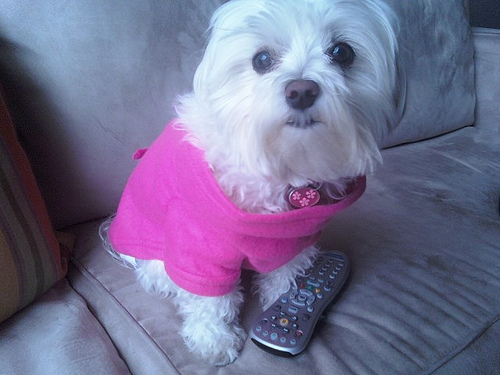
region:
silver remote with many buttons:
[247, 245, 355, 360]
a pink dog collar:
[289, 178, 325, 208]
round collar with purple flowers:
[283, 175, 324, 215]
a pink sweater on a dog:
[103, 117, 370, 277]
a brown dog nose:
[282, 75, 317, 112]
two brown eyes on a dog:
[253, 39, 357, 72]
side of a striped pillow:
[2, 93, 68, 319]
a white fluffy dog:
[103, 2, 412, 364]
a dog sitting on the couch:
[2, 1, 492, 371]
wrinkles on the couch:
[310, 253, 497, 373]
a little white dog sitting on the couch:
[97, 0, 408, 367]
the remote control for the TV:
[247, 245, 354, 360]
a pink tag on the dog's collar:
[285, 184, 323, 209]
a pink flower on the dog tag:
[290, 190, 302, 201]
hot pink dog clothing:
[103, 117, 370, 302]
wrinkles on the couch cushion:
[306, 249, 493, 374]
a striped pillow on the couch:
[0, 95, 72, 326]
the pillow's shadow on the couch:
[0, 35, 93, 231]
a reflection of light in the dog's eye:
[260, 55, 268, 64]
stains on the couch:
[421, 182, 498, 228]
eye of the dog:
[308, 34, 359, 59]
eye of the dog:
[246, 43, 277, 66]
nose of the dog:
[265, 70, 314, 110]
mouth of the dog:
[282, 115, 320, 132]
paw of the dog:
[207, 333, 244, 362]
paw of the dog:
[256, 266, 293, 305]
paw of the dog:
[140, 256, 180, 296]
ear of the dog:
[175, 29, 243, 119]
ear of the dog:
[389, 62, 404, 81]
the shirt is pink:
[175, 230, 229, 255]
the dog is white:
[94, 1, 418, 373]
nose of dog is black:
[282, 73, 324, 112]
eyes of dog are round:
[245, 32, 364, 77]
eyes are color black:
[246, 37, 359, 77]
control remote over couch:
[244, 237, 361, 359]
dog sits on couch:
[86, 5, 423, 367]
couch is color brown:
[0, 0, 499, 370]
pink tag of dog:
[281, 178, 324, 213]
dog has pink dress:
[94, 0, 416, 363]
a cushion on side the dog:
[0, 97, 106, 334]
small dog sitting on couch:
[108, 8, 405, 373]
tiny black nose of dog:
[278, 77, 325, 112]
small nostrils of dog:
[284, 81, 323, 100]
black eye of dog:
[235, 47, 280, 71]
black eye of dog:
[317, 37, 358, 67]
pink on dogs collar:
[295, 184, 321, 207]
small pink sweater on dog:
[72, 118, 388, 290]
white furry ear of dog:
[354, 0, 407, 52]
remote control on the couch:
[250, 252, 362, 361]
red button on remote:
[298, 280, 305, 289]